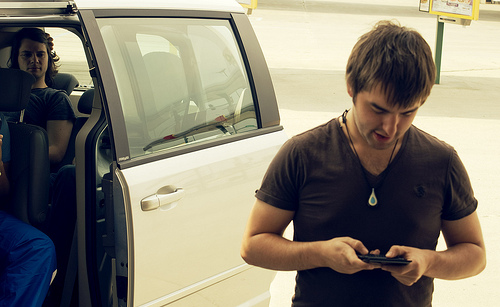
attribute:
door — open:
[2, 17, 182, 305]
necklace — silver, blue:
[349, 120, 413, 220]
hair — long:
[348, 15, 443, 104]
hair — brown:
[347, 18, 435, 109]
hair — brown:
[4, 24, 60, 78]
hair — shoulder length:
[40, 34, 73, 71]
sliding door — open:
[69, 7, 292, 304]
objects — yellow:
[410, 3, 484, 55]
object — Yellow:
[426, 2, 479, 26]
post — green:
[431, 24, 447, 79]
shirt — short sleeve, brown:
[253, 109, 480, 301]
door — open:
[70, 0, 294, 305]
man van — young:
[5, 25, 54, 95]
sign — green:
[411, 0, 481, 23]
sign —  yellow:
[237, 0, 260, 14]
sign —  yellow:
[415, 0, 484, 30]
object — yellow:
[238, 4, 258, 13]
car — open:
[4, 0, 293, 303]